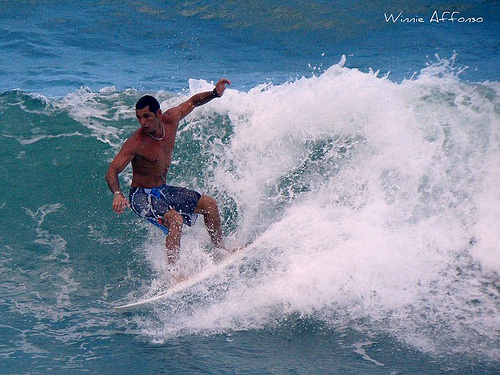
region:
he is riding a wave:
[68, 17, 407, 370]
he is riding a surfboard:
[70, 58, 339, 370]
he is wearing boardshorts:
[77, 46, 282, 311]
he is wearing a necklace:
[130, 83, 194, 149]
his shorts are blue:
[110, 161, 244, 263]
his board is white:
[99, 215, 317, 321]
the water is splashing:
[83, 73, 285, 357]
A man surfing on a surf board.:
[98, 76, 358, 326]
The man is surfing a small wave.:
[95, 52, 494, 327]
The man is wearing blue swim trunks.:
[126, 186, 202, 237]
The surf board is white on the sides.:
[110, 216, 305, 311]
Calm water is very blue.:
[2, 4, 499, 95]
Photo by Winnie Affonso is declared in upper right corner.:
[378, 7, 485, 27]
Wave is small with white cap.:
[240, 54, 499, 326]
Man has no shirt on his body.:
[105, 77, 232, 215]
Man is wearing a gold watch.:
[110, 191, 124, 195]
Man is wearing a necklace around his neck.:
[142, 120, 167, 142]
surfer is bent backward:
[99, 70, 256, 292]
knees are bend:
[157, 191, 222, 238]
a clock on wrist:
[108, 184, 128, 199]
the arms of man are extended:
[89, 67, 244, 218]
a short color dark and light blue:
[122, 181, 204, 239]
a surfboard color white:
[99, 225, 296, 319]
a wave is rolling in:
[0, 45, 499, 358]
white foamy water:
[231, 68, 484, 330]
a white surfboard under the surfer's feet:
[110, 203, 302, 321]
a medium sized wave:
[2, 57, 499, 341]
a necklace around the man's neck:
[140, 123, 168, 141]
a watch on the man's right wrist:
[112, 190, 124, 198]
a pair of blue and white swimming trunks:
[125, 180, 207, 236]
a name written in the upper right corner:
[378, 7, 488, 27]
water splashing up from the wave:
[410, 43, 480, 79]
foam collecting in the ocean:
[347, 334, 398, 372]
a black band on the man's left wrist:
[210, 83, 223, 100]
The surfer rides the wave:
[73, 39, 339, 332]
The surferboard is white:
[110, 213, 338, 323]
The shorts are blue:
[116, 175, 246, 246]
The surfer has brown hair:
[111, 75, 166, 151]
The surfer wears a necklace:
[126, 109, 181, 153]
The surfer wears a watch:
[106, 184, 129, 197]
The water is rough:
[85, 35, 475, 367]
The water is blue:
[121, 22, 314, 60]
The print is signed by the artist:
[379, 16, 498, 28]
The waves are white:
[201, 59, 431, 301]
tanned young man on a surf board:
[105, 78, 237, 283]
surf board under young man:
[112, 206, 297, 308]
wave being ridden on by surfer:
[0, 53, 497, 345]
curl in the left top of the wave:
[0, 87, 131, 192]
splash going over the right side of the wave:
[416, 50, 470, 82]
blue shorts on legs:
[127, 181, 202, 234]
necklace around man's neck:
[151, 120, 165, 140]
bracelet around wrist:
[111, 188, 121, 197]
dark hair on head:
[134, 94, 160, 114]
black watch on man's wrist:
[212, 85, 223, 97]